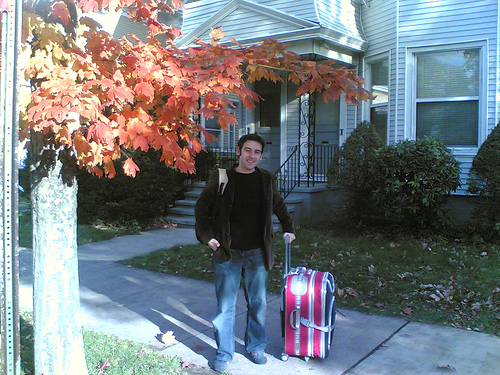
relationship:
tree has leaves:
[21, 0, 376, 373] [24, 0, 378, 179]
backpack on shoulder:
[191, 166, 232, 249] [208, 169, 232, 194]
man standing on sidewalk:
[192, 134, 298, 373] [17, 246, 499, 373]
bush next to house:
[365, 137, 459, 216] [165, 1, 500, 231]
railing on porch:
[272, 77, 340, 201] [175, 54, 354, 192]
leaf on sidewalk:
[159, 328, 178, 348] [17, 246, 499, 373]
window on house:
[405, 39, 488, 152] [165, 1, 500, 231]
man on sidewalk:
[192, 134, 298, 373] [17, 246, 499, 373]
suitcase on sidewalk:
[281, 234, 337, 363] [17, 246, 499, 373]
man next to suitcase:
[192, 134, 298, 373] [281, 234, 337, 363]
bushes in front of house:
[327, 115, 499, 226] [165, 1, 500, 231]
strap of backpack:
[218, 167, 229, 199] [191, 166, 232, 249]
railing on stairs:
[272, 77, 340, 201] [167, 181, 301, 234]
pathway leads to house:
[78, 225, 200, 261] [165, 1, 500, 231]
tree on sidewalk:
[21, 0, 376, 373] [17, 246, 499, 373]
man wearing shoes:
[192, 134, 298, 373] [208, 350, 268, 372]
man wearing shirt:
[192, 134, 298, 373] [232, 167, 264, 249]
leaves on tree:
[24, 0, 378, 179] [21, 0, 376, 373]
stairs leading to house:
[167, 181, 301, 234] [165, 1, 500, 231]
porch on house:
[175, 54, 354, 192] [165, 1, 500, 231]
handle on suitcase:
[284, 235, 293, 277] [281, 234, 337, 363]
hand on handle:
[283, 231, 297, 244] [284, 235, 293, 277]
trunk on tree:
[30, 137, 89, 374] [21, 0, 376, 373]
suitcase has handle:
[281, 234, 337, 363] [284, 235, 293, 277]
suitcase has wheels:
[281, 234, 337, 363] [279, 349, 290, 362]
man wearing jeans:
[192, 134, 298, 373] [210, 247, 272, 357]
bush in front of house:
[365, 137, 459, 216] [165, 1, 500, 231]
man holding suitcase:
[192, 134, 298, 373] [281, 234, 337, 363]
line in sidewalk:
[336, 320, 414, 374] [17, 246, 499, 373]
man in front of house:
[192, 134, 298, 373] [165, 1, 500, 231]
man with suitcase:
[192, 134, 298, 373] [281, 234, 337, 363]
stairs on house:
[167, 181, 301, 234] [165, 1, 500, 231]